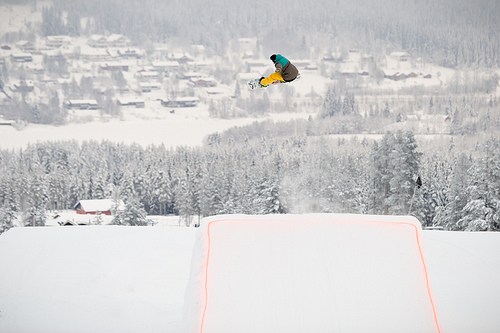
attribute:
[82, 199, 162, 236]
house — red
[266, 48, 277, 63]
hat — dark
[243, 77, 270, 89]
snowboard — white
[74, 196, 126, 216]
building — brown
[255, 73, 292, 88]
pants — yellow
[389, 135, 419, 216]
pine tree — tall, green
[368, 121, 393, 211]
pine tree — tall, green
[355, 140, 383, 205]
pine tree — green, tall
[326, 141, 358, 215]
pine tree — green, tall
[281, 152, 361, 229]
pine tree — tall, green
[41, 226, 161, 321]
snow — white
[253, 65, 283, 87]
snow pants — yellow 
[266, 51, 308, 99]
coat — brown 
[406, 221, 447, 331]
line — orange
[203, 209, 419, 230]
line — orange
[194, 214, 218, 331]
line — orange